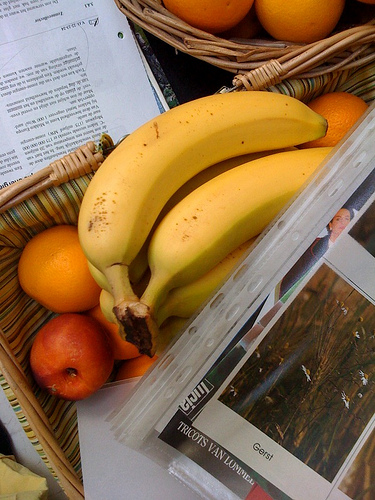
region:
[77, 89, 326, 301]
banana is next to banana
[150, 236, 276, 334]
banana is next to banana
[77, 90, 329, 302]
banana is next to orange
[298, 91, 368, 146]
orange is next to banana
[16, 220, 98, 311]
orange is next to banana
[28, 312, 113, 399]
apricot is next to orange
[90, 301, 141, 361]
orange is next to apricot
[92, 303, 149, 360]
orange is next to banana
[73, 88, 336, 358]
Bunch of yellow bananas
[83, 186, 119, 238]
Brown spots on a banana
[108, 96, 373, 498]
Sheets of paper in page holders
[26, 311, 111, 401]
Overripe red apple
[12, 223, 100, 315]
Unpeeled unripe orange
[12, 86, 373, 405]
Fruit in a basket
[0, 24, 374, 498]
Striped cloth basket with wood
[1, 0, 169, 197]
Stack of typed papers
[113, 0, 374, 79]
Two oranges in a basket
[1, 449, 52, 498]
Crumpled piece of paper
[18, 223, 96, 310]
Small fruit in a basket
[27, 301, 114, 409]
Small fruit in a basket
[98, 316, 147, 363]
Small fruit in a basket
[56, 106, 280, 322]
Small fruit in a basket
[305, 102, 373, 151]
Small fruit in a basket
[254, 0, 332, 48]
Small fruit in a basket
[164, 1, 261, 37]
Small fruit in a basket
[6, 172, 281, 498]
Fruit in a brown basket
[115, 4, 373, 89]
Fruit in a brown basket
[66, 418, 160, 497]
Small white peice of paper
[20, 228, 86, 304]
The orange in the basket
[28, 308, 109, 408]
The apricot in the basket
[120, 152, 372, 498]
The reading material in the basket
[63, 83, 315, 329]
The bananas in the basket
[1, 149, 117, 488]
The basket is made of wicker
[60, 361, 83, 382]
The stem of the fruit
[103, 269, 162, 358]
The stem of the banana's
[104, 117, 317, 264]
The banana's are the color yellow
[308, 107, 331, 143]
The end of the banana's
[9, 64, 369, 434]
The fruit in the basket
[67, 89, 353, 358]
A bunch of bananas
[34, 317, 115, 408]
An orange in a basket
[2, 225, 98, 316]
An orange in the basket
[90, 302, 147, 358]
An orange in the basket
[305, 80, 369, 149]
An orange in the basket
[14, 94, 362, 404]
A bunch of fruit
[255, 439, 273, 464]
The word Gerst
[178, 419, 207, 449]
The word Tricots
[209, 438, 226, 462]
The word Van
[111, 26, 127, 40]
A hole in the paper